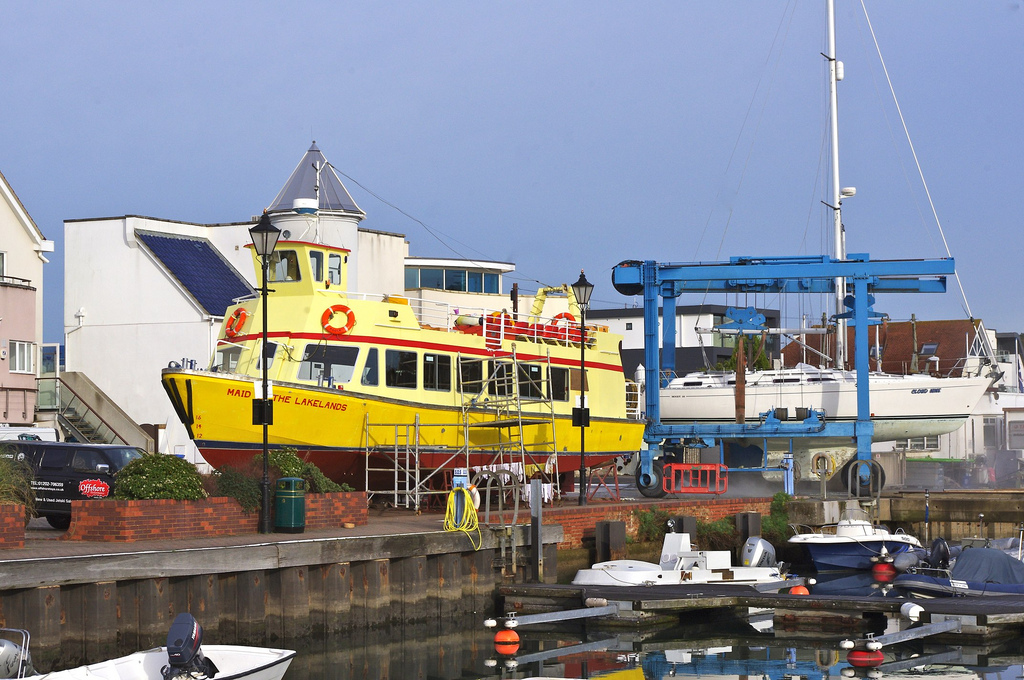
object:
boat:
[633, 0, 987, 448]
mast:
[814, 0, 858, 368]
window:
[466, 271, 483, 293]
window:
[484, 273, 500, 294]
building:
[63, 141, 584, 491]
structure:
[610, 251, 955, 495]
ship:
[158, 239, 651, 508]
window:
[518, 364, 543, 399]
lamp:
[247, 205, 282, 270]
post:
[249, 255, 277, 530]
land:
[0, 494, 1024, 680]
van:
[0, 438, 153, 528]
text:
[30, 480, 73, 503]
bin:
[274, 477, 306, 533]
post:
[247, 205, 283, 533]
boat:
[616, 250, 1004, 452]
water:
[392, 619, 461, 662]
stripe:
[232, 335, 631, 404]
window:
[36, 345, 56, 378]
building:
[0, 172, 57, 454]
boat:
[156, 241, 651, 495]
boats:
[534, 516, 1022, 619]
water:
[288, 593, 468, 674]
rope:
[443, 477, 482, 531]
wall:
[101, 527, 512, 624]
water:
[350, 627, 495, 677]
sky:
[285, 0, 610, 117]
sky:
[0, 0, 421, 113]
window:
[298, 344, 361, 383]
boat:
[868, 532, 1024, 617]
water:
[402, 592, 760, 675]